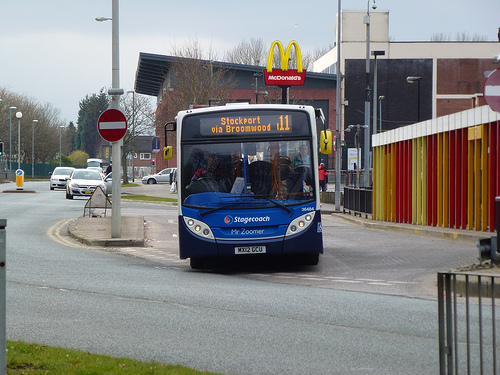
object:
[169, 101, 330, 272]
bus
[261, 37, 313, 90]
sign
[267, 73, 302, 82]
mcdonald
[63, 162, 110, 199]
car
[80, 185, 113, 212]
sign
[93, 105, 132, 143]
sign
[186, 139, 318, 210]
windshield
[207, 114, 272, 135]
stockport via broomw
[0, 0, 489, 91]
sky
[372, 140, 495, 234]
wall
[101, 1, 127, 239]
pole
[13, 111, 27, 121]
lamp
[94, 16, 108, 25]
streetlight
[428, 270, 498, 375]
fence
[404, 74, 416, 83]
streetlight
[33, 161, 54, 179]
fence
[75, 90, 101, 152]
tree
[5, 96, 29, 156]
trees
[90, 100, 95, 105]
leaves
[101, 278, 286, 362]
street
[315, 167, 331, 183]
jacket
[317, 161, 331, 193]
person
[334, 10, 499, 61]
roof